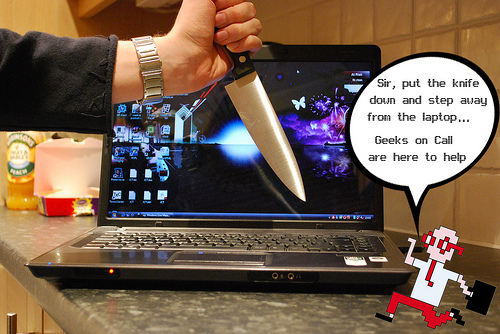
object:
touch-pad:
[165, 251, 271, 263]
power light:
[107, 268, 114, 273]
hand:
[165, 0, 264, 96]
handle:
[212, 32, 255, 79]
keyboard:
[80, 230, 388, 254]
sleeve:
[0, 28, 117, 137]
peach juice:
[5, 133, 36, 211]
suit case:
[467, 280, 496, 317]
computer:
[23, 43, 416, 291]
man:
[375, 224, 470, 328]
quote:
[343, 51, 499, 238]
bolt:
[238, 54, 247, 63]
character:
[375, 225, 495, 330]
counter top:
[0, 205, 499, 332]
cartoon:
[341, 51, 498, 330]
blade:
[220, 70, 307, 202]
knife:
[213, 20, 306, 204]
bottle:
[6, 132, 47, 210]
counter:
[0, 210, 499, 333]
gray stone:
[128, 308, 143, 317]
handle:
[4, 312, 18, 332]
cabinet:
[0, 264, 62, 333]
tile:
[340, 0, 375, 45]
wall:
[255, 0, 498, 248]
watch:
[132, 36, 165, 103]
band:
[132, 34, 164, 105]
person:
[0, 0, 265, 137]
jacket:
[0, 26, 117, 134]